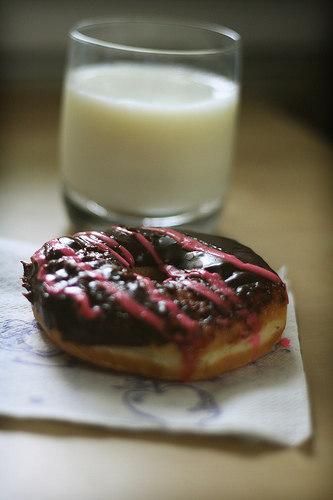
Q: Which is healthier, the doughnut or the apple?
A: The apple is healthier than the doughnut.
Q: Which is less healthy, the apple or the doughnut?
A: The doughnut is less healthy than the apple.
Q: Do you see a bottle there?
A: No, there are no bottles.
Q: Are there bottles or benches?
A: No, there are no bottles or benches.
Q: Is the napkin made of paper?
A: Yes, the napkin is made of paper.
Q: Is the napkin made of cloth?
A: No, the napkin is made of paper.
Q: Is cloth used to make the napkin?
A: No, the napkin is made of paper.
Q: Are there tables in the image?
A: Yes, there is a table.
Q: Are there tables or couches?
A: Yes, there is a table.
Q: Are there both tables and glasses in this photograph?
A: Yes, there are both a table and glasses.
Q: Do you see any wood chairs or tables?
A: Yes, there is a wood table.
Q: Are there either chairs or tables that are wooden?
A: Yes, the table is wooden.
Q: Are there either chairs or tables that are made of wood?
A: Yes, the table is made of wood.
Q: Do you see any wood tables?
A: Yes, there is a wood table.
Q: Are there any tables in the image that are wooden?
A: Yes, there is a wood table.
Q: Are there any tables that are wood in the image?
A: Yes, there is a wood table.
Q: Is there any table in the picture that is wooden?
A: Yes, there is a table that is wooden.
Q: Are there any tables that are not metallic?
A: Yes, there is a wooden table.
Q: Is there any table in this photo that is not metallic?
A: Yes, there is a wooden table.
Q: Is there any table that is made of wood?
A: Yes, there is a table that is made of wood.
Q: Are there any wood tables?
A: Yes, there is a table that is made of wood.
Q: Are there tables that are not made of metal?
A: Yes, there is a table that is made of wood.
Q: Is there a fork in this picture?
A: No, there are no forks.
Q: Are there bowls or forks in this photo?
A: No, there are no forks or bowls.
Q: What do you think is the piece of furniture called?
A: The piece of furniture is a table.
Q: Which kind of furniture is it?
A: The piece of furniture is a table.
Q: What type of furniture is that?
A: This is a table.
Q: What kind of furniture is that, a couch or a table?
A: This is a table.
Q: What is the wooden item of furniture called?
A: The piece of furniture is a table.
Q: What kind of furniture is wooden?
A: The furniture is a table.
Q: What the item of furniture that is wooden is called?
A: The piece of furniture is a table.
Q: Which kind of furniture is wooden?
A: The furniture is a table.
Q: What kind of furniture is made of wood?
A: The furniture is a table.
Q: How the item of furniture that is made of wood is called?
A: The piece of furniture is a table.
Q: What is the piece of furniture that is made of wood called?
A: The piece of furniture is a table.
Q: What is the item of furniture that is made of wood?
A: The piece of furniture is a table.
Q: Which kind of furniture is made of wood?
A: The furniture is a table.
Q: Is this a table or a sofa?
A: This is a table.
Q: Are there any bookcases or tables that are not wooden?
A: No, there is a table but it is wooden.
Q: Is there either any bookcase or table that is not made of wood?
A: No, there is a table but it is made of wood.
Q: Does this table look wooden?
A: Yes, the table is wooden.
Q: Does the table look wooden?
A: Yes, the table is wooden.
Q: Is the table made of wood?
A: Yes, the table is made of wood.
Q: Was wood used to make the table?
A: Yes, the table is made of wood.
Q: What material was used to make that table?
A: The table is made of wood.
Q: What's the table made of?
A: The table is made of wood.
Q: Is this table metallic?
A: No, the table is wooden.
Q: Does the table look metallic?
A: No, the table is wooden.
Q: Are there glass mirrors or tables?
A: No, there is a table but it is wooden.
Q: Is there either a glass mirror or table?
A: No, there is a table but it is wooden.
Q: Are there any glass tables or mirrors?
A: No, there is a table but it is wooden.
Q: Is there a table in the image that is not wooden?
A: No, there is a table but it is wooden.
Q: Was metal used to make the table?
A: No, the table is made of wood.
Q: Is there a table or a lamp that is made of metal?
A: No, there is a table but it is made of wood.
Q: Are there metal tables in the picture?
A: No, there is a table but it is made of wood.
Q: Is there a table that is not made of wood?
A: No, there is a table but it is made of wood.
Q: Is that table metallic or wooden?
A: The table is wooden.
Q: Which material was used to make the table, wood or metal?
A: The table is made of wood.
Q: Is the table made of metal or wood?
A: The table is made of wood.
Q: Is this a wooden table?
A: Yes, this is a wooden table.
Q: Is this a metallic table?
A: No, this is a wooden table.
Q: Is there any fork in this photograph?
A: No, there are no forks.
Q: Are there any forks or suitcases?
A: No, there are no forks or suitcases.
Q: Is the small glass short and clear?
A: Yes, the glass is short and clear.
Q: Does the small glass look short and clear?
A: Yes, the glass is short and clear.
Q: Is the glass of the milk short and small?
A: Yes, the glass is short and small.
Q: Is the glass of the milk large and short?
A: No, the glass is short but small.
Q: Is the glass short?
A: Yes, the glass is short.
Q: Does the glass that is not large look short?
A: Yes, the glass is short.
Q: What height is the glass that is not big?
A: The glass is short.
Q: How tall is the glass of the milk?
A: The glass is short.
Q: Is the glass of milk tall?
A: No, the glass is short.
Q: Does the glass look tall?
A: No, the glass is short.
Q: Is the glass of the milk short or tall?
A: The glass is short.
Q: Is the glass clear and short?
A: Yes, the glass is clear and short.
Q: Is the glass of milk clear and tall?
A: No, the glass is clear but short.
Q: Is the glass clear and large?
A: No, the glass is clear but small.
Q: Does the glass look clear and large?
A: No, the glass is clear but small.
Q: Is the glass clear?
A: Yes, the glass is clear.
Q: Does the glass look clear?
A: Yes, the glass is clear.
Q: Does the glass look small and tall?
A: No, the glass is small but short.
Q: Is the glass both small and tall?
A: No, the glass is small but short.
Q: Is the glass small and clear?
A: Yes, the glass is small and clear.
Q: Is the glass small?
A: Yes, the glass is small.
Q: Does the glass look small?
A: Yes, the glass is small.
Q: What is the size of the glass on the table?
A: The glass is small.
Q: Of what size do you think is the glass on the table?
A: The glass is small.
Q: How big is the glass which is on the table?
A: The glass is small.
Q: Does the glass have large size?
A: No, the glass is small.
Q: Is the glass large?
A: No, the glass is small.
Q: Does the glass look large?
A: No, the glass is small.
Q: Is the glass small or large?
A: The glass is small.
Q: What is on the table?
A: The glass is on the table.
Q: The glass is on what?
A: The glass is on the table.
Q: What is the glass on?
A: The glass is on the table.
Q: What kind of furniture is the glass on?
A: The glass is on the table.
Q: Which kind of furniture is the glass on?
A: The glass is on the table.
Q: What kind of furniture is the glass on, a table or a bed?
A: The glass is on a table.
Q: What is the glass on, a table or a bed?
A: The glass is on a table.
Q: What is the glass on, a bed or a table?
A: The glass is on a table.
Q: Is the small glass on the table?
A: Yes, the glass is on the table.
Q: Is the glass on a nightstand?
A: No, the glass is on the table.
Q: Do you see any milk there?
A: Yes, there is milk.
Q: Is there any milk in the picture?
A: Yes, there is milk.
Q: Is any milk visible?
A: Yes, there is milk.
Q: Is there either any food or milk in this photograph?
A: Yes, there is milk.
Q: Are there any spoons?
A: No, there are no spoons.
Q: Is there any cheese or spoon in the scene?
A: No, there are no spoons or cheese.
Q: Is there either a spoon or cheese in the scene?
A: No, there are no spoons or cheese.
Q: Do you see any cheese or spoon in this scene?
A: No, there are no spoons or cheese.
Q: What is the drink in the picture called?
A: The drink is milk.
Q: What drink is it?
A: The drink is milk.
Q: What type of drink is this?
A: This is milk.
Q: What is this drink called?
A: This is milk.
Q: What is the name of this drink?
A: This is milk.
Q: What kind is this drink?
A: This is milk.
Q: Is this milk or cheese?
A: This is milk.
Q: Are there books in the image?
A: No, there are no books.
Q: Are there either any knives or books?
A: No, there are no books or knives.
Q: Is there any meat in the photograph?
A: No, there is no meat.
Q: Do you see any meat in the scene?
A: No, there is no meat.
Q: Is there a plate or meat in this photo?
A: No, there are no meat or plates.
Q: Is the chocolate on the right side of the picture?
A: Yes, the chocolate is on the right of the image.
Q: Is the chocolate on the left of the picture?
A: No, the chocolate is on the right of the image.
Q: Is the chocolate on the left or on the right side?
A: The chocolate is on the right of the image.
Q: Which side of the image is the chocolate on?
A: The chocolate is on the right of the image.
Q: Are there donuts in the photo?
A: Yes, there is a donut.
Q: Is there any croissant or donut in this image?
A: Yes, there is a donut.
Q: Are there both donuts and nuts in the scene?
A: No, there is a donut but no nuts.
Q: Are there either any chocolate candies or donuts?
A: Yes, there is a chocolate donut.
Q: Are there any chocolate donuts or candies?
A: Yes, there is a chocolate donut.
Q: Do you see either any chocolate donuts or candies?
A: Yes, there is a chocolate donut.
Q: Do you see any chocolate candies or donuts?
A: Yes, there is a chocolate donut.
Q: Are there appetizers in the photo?
A: No, there are no appetizers.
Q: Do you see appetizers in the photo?
A: No, there are no appetizers.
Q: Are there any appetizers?
A: No, there are no appetizers.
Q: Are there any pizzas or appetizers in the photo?
A: No, there are no appetizers or pizzas.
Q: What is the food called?
A: The food is a donut.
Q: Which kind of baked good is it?
A: The food is a donut.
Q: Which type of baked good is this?
A: This is a donut.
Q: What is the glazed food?
A: The food is a donut.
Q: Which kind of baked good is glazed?
A: The baked good is a donut.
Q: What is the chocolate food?
A: The food is a donut.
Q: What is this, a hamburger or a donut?
A: This is a donut.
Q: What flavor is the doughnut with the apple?
A: This is a chocolate donut.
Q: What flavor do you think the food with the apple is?
A: This is a chocolate donut.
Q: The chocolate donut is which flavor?
A: This is a chocolate donut.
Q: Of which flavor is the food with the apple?
A: This is a chocolate donut.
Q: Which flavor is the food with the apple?
A: This is a chocolate donut.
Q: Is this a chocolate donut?
A: Yes, this is a chocolate donut.